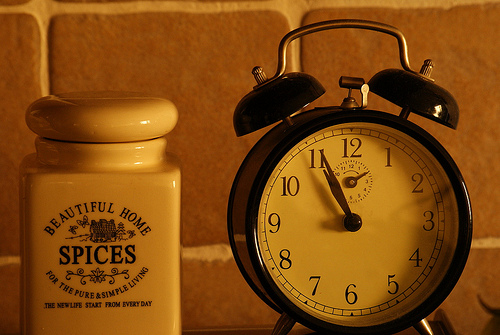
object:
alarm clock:
[228, 18, 474, 334]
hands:
[318, 147, 364, 232]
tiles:
[0, 1, 500, 334]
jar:
[18, 136, 182, 334]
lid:
[25, 91, 179, 143]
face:
[257, 121, 460, 327]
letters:
[42, 200, 153, 309]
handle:
[251, 19, 435, 85]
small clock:
[331, 159, 374, 203]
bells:
[230, 58, 460, 137]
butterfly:
[76, 215, 90, 229]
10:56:
[257, 120, 447, 316]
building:
[88, 218, 118, 241]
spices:
[60, 244, 137, 264]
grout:
[0, 0, 499, 265]